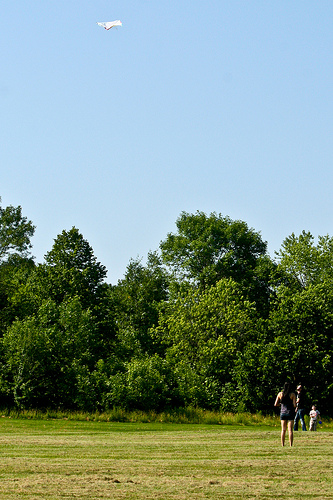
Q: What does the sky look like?
A: Clear.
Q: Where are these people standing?
A: Field.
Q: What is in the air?
A: Toy plane.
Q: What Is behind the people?
A: Trees.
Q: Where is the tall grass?
A: Tree line.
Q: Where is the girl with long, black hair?
A: Foreground.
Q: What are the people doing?
A: Watching.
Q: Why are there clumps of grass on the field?
A: Freshly mowed.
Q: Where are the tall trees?
A: Behind the people?.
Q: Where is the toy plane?
A: In the air.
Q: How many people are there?
A: Three.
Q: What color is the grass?
A: Green.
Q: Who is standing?
A: People.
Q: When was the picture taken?
A: In the daytime.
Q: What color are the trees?
A: Dark green.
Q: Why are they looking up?
A: To see the kite.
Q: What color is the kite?
A: White.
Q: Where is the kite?
A: In the sky.